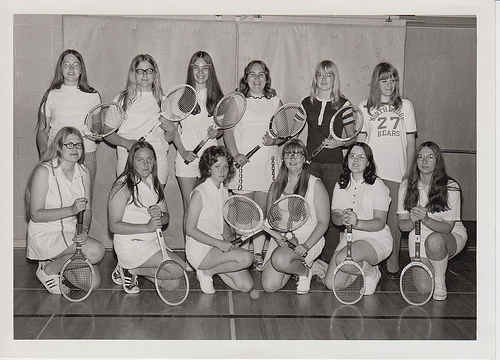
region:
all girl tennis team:
[16, 47, 499, 310]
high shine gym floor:
[28, 299, 478, 342]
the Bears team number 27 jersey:
[370, 108, 415, 153]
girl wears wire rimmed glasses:
[46, 39, 95, 91]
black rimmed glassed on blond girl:
[115, 51, 165, 113]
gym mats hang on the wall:
[12, 11, 400, 113]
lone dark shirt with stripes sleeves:
[288, 80, 360, 161]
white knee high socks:
[425, 244, 471, 300]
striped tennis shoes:
[31, 256, 148, 311]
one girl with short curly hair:
[186, 141, 241, 194]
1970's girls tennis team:
[52, 41, 444, 298]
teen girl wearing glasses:
[26, 126, 93, 233]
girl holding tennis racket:
[119, 137, 180, 299]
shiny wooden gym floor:
[76, 299, 358, 347]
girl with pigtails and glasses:
[257, 136, 322, 263]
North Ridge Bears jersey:
[366, 99, 422, 153]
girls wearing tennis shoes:
[27, 246, 164, 308]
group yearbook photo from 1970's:
[47, 35, 461, 327]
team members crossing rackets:
[186, 138, 333, 321]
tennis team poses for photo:
[43, 31, 465, 293]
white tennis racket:
[145, 202, 195, 311]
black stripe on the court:
[190, 301, 255, 333]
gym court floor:
[116, 302, 188, 329]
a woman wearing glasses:
[273, 130, 318, 188]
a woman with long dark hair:
[395, 138, 457, 242]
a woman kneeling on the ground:
[18, 115, 95, 328]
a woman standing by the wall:
[182, 42, 228, 121]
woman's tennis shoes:
[104, 248, 157, 307]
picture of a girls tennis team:
[36, 33, 478, 318]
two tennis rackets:
[207, 180, 322, 265]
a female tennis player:
[357, 57, 413, 284]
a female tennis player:
[387, 141, 468, 310]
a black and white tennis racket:
[58, 204, 93, 304]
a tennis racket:
[76, 98, 122, 146]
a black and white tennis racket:
[127, 82, 196, 149]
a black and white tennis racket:
[144, 209, 191, 306]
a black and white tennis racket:
[222, 192, 262, 247]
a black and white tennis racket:
[182, 92, 247, 168]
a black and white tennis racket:
[233, 101, 305, 170]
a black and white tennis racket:
[238, 192, 308, 248]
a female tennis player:
[41, 49, 123, 159]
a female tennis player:
[25, 126, 107, 294]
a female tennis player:
[106, 49, 197, 186]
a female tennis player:
[105, 140, 191, 307]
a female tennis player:
[179, 147, 262, 297]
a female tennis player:
[171, 49, 246, 214]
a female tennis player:
[219, 58, 309, 190]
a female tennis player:
[259, 135, 331, 295]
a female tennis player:
[324, 142, 392, 305]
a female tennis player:
[301, 60, 361, 182]